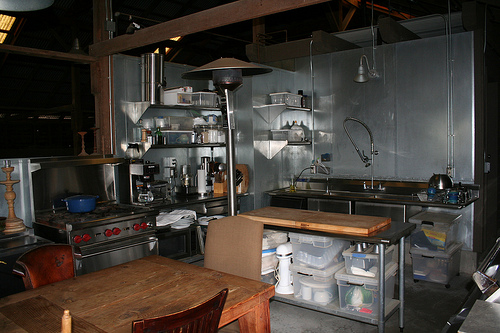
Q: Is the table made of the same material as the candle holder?
A: Yes, both the table and the candle holder are made of wood.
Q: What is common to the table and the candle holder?
A: The material, both the table and the candle holder are wooden.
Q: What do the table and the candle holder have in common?
A: The material, both the table and the candle holder are wooden.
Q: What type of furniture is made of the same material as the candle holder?
A: The table is made of the same material as the candle holder.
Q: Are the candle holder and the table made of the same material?
A: Yes, both the candle holder and the table are made of wood.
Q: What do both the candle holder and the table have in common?
A: The material, both the candle holder and the table are wooden.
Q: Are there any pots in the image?
A: Yes, there is a pot.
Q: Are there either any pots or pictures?
A: Yes, there is a pot.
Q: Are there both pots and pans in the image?
A: No, there is a pot but no pans.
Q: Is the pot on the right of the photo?
A: No, the pot is on the left of the image.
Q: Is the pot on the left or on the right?
A: The pot is on the left of the image.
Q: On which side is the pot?
A: The pot is on the left of the image.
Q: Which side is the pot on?
A: The pot is on the left of the image.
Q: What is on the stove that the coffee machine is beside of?
A: The pot is on the stove.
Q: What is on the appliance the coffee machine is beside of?
A: The pot is on the stove.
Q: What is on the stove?
A: The pot is on the stove.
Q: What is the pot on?
A: The pot is on the stove.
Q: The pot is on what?
A: The pot is on the stove.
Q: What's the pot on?
A: The pot is on the stove.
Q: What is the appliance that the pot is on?
A: The appliance is a stove.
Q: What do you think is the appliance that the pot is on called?
A: The appliance is a stove.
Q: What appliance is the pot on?
A: The pot is on the stove.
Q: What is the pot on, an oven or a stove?
A: The pot is on a stove.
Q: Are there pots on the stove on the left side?
A: Yes, there is a pot on the stove.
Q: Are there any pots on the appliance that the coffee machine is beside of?
A: Yes, there is a pot on the stove.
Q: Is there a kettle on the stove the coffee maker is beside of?
A: No, there is a pot on the stove.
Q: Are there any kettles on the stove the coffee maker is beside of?
A: No, there is a pot on the stove.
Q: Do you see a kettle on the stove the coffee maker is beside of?
A: No, there is a pot on the stove.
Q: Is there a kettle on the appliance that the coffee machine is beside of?
A: No, there is a pot on the stove.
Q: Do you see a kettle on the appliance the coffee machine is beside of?
A: No, there is a pot on the stove.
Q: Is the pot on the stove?
A: Yes, the pot is on the stove.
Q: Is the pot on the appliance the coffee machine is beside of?
A: Yes, the pot is on the stove.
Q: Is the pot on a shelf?
A: No, the pot is on the stove.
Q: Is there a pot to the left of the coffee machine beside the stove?
A: Yes, there is a pot to the left of the coffee maker.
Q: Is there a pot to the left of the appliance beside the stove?
A: Yes, there is a pot to the left of the coffee maker.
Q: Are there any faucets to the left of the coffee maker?
A: No, there is a pot to the left of the coffee maker.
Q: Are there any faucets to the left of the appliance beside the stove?
A: No, there is a pot to the left of the coffee maker.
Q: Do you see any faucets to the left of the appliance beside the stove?
A: No, there is a pot to the left of the coffee maker.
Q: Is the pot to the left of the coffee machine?
A: Yes, the pot is to the left of the coffee machine.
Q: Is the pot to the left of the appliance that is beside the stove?
A: Yes, the pot is to the left of the coffee machine.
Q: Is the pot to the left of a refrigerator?
A: No, the pot is to the left of the coffee machine.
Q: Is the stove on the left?
A: Yes, the stove is on the left of the image.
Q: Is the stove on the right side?
A: No, the stove is on the left of the image.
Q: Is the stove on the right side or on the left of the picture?
A: The stove is on the left of the image.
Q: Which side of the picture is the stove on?
A: The stove is on the left of the image.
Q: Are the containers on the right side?
A: Yes, the containers are on the right of the image.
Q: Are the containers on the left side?
A: No, the containers are on the right of the image.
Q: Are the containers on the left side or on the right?
A: The containers are on the right of the image.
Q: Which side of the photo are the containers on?
A: The containers are on the right of the image.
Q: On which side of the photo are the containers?
A: The containers are on the right of the image.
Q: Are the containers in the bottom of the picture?
A: Yes, the containers are in the bottom of the image.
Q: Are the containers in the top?
A: No, the containers are in the bottom of the image.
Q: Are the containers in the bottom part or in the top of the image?
A: The containers are in the bottom of the image.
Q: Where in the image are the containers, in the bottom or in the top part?
A: The containers are in the bottom of the image.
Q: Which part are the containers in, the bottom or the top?
A: The containers are in the bottom of the image.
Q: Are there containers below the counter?
A: Yes, there are containers below the counter.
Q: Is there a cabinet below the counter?
A: No, there are containers below the counter.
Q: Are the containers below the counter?
A: Yes, the containers are below the counter.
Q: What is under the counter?
A: The containers are under the counter.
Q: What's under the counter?
A: The containers are under the counter.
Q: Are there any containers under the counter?
A: Yes, there are containers under the counter.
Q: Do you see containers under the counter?
A: Yes, there are containers under the counter.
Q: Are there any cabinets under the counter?
A: No, there are containers under the counter.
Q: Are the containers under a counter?
A: Yes, the containers are under a counter.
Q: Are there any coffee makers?
A: Yes, there is a coffee maker.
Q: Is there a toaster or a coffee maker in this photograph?
A: Yes, there is a coffee maker.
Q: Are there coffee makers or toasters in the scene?
A: Yes, there is a coffee maker.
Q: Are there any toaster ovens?
A: No, there are no toaster ovens.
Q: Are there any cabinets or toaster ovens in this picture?
A: No, there are no toaster ovens or cabinets.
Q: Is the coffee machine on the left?
A: Yes, the coffee machine is on the left of the image.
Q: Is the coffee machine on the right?
A: No, the coffee machine is on the left of the image.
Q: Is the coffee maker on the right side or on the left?
A: The coffee maker is on the left of the image.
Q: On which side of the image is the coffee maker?
A: The coffee maker is on the left of the image.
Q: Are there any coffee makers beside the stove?
A: Yes, there is a coffee maker beside the stove.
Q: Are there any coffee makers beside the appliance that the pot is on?
A: Yes, there is a coffee maker beside the stove.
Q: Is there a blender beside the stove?
A: No, there is a coffee maker beside the stove.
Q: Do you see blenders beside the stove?
A: No, there is a coffee maker beside the stove.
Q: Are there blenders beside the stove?
A: No, there is a coffee maker beside the stove.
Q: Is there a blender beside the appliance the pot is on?
A: No, there is a coffee maker beside the stove.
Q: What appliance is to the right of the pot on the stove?
A: The appliance is a coffee maker.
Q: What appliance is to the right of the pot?
A: The appliance is a coffee maker.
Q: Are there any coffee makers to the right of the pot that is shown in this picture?
A: Yes, there is a coffee maker to the right of the pot.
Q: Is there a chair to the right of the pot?
A: No, there is a coffee maker to the right of the pot.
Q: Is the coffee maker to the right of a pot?
A: Yes, the coffee maker is to the right of a pot.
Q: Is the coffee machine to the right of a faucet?
A: No, the coffee machine is to the right of a pot.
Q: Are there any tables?
A: Yes, there is a table.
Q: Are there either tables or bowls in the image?
A: Yes, there is a table.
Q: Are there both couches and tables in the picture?
A: No, there is a table but no couches.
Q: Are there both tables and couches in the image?
A: No, there is a table but no couches.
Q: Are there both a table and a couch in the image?
A: No, there is a table but no couches.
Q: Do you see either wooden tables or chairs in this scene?
A: Yes, there is a wood table.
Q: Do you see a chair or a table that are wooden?
A: Yes, the table is wooden.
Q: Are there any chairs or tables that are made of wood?
A: Yes, the table is made of wood.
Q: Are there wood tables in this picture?
A: Yes, there is a wood table.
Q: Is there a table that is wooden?
A: Yes, there is a table that is wooden.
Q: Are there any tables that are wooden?
A: Yes, there is a table that is wooden.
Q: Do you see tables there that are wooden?
A: Yes, there is a table that is wooden.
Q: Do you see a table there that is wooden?
A: Yes, there is a table that is wooden.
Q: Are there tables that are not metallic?
A: Yes, there is a wooden table.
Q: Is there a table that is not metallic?
A: Yes, there is a wooden table.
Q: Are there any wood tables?
A: Yes, there is a table that is made of wood.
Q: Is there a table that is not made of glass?
A: Yes, there is a table that is made of wood.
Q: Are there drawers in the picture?
A: No, there are no drawers.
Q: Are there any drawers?
A: No, there are no drawers.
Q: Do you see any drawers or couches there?
A: No, there are no drawers or couches.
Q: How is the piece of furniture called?
A: The piece of furniture is a table.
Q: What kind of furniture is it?
A: The piece of furniture is a table.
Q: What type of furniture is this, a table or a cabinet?
A: This is a table.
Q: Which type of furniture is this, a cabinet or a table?
A: This is a table.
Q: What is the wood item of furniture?
A: The piece of furniture is a table.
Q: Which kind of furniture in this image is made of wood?
A: The furniture is a table.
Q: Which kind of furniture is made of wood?
A: The furniture is a table.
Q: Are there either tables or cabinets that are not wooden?
A: No, there is a table but it is wooden.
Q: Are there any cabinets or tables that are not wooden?
A: No, there is a table but it is wooden.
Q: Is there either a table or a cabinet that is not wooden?
A: No, there is a table but it is wooden.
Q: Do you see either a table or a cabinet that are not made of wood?
A: No, there is a table but it is made of wood.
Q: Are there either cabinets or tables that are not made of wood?
A: No, there is a table but it is made of wood.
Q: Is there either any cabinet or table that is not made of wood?
A: No, there is a table but it is made of wood.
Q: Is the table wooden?
A: Yes, the table is wooden.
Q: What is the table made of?
A: The table is made of wood.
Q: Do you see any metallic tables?
A: No, there is a table but it is wooden.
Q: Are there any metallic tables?
A: No, there is a table but it is wooden.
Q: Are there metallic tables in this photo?
A: No, there is a table but it is wooden.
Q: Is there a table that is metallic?
A: No, there is a table but it is wooden.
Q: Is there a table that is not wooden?
A: No, there is a table but it is wooden.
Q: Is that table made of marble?
A: No, the table is made of wood.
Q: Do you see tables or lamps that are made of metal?
A: No, there is a table but it is made of wood.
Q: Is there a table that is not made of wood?
A: No, there is a table but it is made of wood.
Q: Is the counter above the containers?
A: Yes, the counter is above the containers.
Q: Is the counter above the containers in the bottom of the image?
A: Yes, the counter is above the containers.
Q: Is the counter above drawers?
A: No, the counter is above the containers.